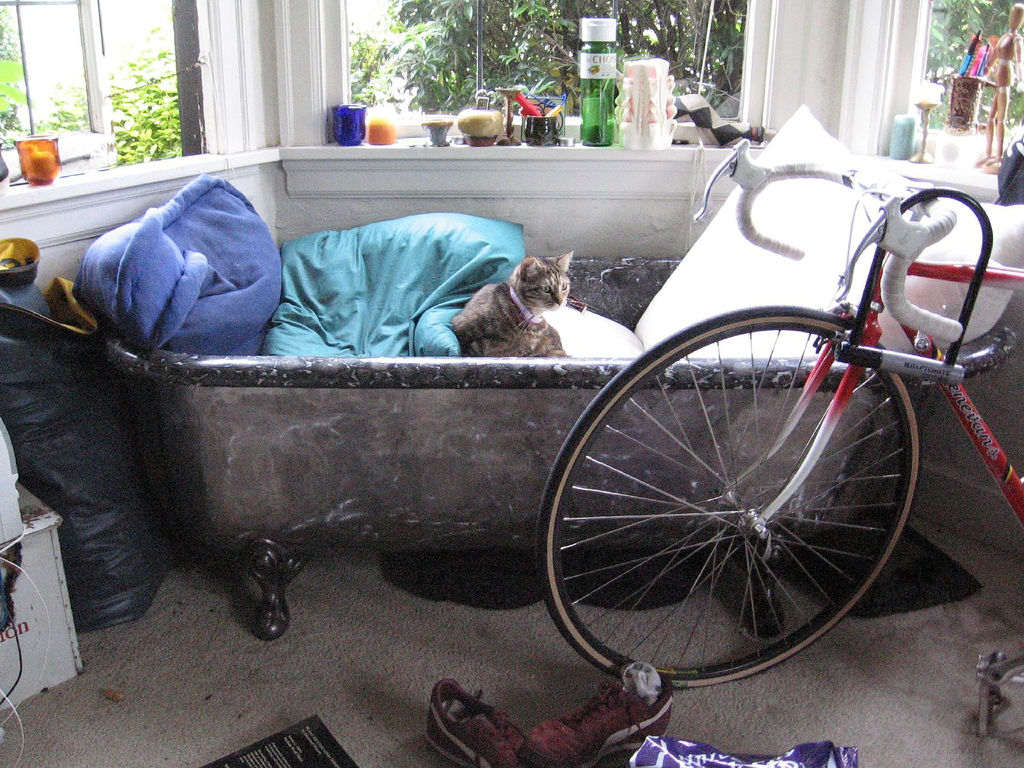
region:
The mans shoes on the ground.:
[411, 644, 688, 766]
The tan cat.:
[457, 260, 612, 394]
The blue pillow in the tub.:
[94, 177, 276, 351]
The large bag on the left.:
[9, 271, 175, 661]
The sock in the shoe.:
[628, 652, 663, 704]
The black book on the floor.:
[190, 718, 358, 766]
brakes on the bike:
[677, 130, 767, 232]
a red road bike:
[534, 101, 1019, 727]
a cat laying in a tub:
[436, 241, 627, 396]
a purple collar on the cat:
[497, 272, 537, 336]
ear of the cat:
[507, 245, 562, 278]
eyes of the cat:
[541, 276, 580, 300]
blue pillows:
[67, 182, 521, 385]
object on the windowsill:
[318, 105, 363, 150]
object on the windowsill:
[902, 121, 932, 157]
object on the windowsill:
[624, 63, 675, 153]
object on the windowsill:
[520, 120, 550, 152]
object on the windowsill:
[665, 94, 724, 146]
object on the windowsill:
[472, 108, 507, 143]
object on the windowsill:
[51, 143, 103, 175]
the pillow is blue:
[74, 174, 278, 356]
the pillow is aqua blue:
[258, 212, 525, 364]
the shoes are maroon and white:
[428, 661, 667, 764]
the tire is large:
[535, 306, 922, 690]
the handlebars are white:
[694, 136, 963, 345]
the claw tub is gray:
[100, 253, 1015, 642]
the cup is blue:
[330, 101, 369, 147]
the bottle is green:
[576, 16, 619, 149]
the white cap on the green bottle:
[574, 13, 619, 147]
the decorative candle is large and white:
[612, 56, 680, 151]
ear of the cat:
[552, 241, 582, 284]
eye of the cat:
[551, 277, 577, 291]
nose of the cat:
[544, 282, 573, 309]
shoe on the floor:
[433, 699, 539, 760]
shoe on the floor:
[667, 742, 699, 762]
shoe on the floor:
[975, 651, 1007, 749]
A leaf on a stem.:
[445, 36, 453, 63]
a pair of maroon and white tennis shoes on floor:
[431, 667, 659, 760]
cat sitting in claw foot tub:
[374, 190, 561, 621]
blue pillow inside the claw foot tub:
[100, 188, 278, 360]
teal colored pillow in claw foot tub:
[301, 235, 451, 362]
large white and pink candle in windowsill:
[615, 54, 683, 153]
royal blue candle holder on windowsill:
[330, 99, 369, 147]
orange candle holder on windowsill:
[12, 126, 73, 188]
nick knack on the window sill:
[323, 100, 368, 148]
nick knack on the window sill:
[356, 106, 385, 141]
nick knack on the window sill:
[453, 100, 514, 143]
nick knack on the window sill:
[571, 0, 620, 156]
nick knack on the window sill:
[981, 2, 1014, 208]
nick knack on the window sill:
[879, 103, 918, 165]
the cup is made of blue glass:
[329, 99, 372, 144]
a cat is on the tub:
[454, 262, 578, 364]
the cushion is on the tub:
[284, 214, 523, 380]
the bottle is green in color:
[572, 15, 621, 143]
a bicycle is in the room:
[546, 132, 1018, 695]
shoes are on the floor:
[422, 655, 678, 761]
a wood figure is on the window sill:
[988, 0, 1023, 187]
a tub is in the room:
[110, 259, 899, 651]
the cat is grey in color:
[446, 253, 580, 370]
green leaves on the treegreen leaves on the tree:
[476, 13, 484, 30]